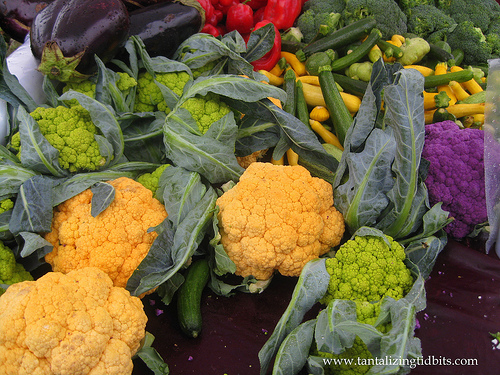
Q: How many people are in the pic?
A: None.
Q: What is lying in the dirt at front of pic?
A: A cucumber.